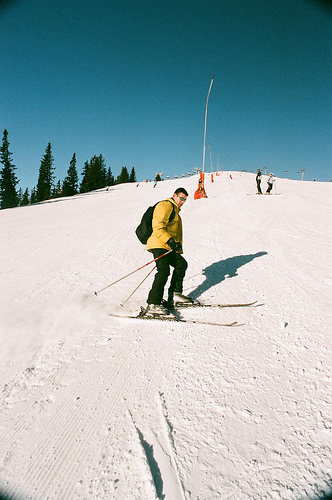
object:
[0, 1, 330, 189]
sky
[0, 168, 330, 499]
snow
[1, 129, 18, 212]
trees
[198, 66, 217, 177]
pole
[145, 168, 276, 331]
people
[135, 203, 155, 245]
backpack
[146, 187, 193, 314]
skier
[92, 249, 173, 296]
ski poles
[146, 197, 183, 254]
jacket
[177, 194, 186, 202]
pair of sunglasses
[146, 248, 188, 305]
pants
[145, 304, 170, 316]
boots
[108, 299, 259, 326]
pair of skis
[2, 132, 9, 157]
leaves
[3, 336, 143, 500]
tracks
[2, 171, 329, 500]
mountain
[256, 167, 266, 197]
person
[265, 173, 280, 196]
person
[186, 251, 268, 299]
shadow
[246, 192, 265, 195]
skis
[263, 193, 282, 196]
skis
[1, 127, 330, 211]
background